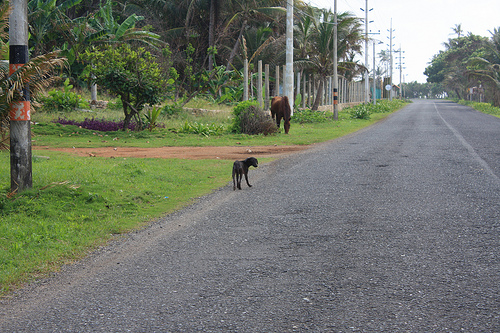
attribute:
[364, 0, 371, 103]
telephone pole — series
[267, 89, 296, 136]
horse — brown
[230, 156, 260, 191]
dog — black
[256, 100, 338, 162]
horse — grazing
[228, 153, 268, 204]
dog — black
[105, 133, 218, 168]
road — brown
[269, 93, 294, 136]
horse — grazing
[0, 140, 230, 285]
grass — green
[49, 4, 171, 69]
trees — palm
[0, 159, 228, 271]
green grass — short, growing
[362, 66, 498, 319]
road — dark grey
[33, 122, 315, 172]
path — dirt, leading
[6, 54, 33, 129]
sign — orange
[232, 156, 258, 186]
dog — black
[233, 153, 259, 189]
dog — small, black, walking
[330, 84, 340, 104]
sign — yellow, black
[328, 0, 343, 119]
pole — metal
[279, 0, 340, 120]
poles — white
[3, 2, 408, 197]
power poles — tall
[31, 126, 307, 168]
dirt road — brown, behind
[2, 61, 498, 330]
road — black, paved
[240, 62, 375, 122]
poles — wooden